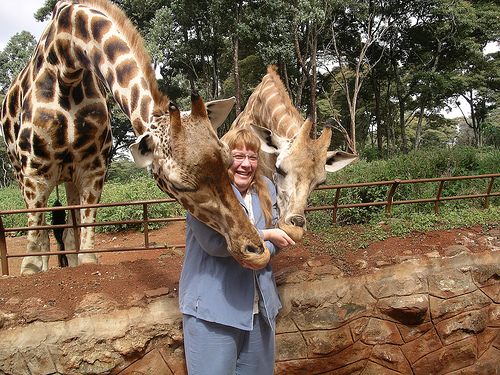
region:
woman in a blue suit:
[179, 128, 281, 373]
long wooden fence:
[1, 176, 498, 276]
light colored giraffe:
[229, 63, 356, 235]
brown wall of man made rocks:
[5, 254, 498, 370]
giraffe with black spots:
[1, 3, 269, 271]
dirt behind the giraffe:
[4, 218, 190, 276]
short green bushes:
[1, 148, 495, 233]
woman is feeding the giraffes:
[150, 97, 323, 357]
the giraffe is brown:
[114, 61, 337, 322]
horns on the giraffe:
[165, 95, 221, 163]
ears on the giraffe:
[131, 98, 234, 170]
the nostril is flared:
[239, 234, 262, 259]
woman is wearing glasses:
[234, 151, 256, 164]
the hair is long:
[227, 132, 274, 237]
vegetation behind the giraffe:
[5, 87, 480, 202]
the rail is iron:
[0, 181, 497, 253]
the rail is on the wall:
[11, 192, 493, 367]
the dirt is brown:
[23, 265, 180, 301]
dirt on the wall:
[10, 270, 198, 371]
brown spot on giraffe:
[7, 86, 20, 117]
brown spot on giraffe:
[17, 66, 34, 102]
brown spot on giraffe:
[31, 43, 48, 79]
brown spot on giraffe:
[44, 44, 62, 68]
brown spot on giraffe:
[31, 65, 57, 105]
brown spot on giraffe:
[18, 127, 34, 153]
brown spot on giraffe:
[72, 97, 108, 153]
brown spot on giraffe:
[101, 34, 130, 61]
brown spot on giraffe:
[115, 59, 138, 90]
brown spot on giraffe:
[128, 80, 141, 114]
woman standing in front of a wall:
[180, 129, 285, 374]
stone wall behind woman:
[0, 231, 497, 373]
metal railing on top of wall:
[306, 172, 498, 227]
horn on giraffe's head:
[167, 102, 182, 134]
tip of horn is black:
[168, 102, 176, 110]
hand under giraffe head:
[259, 228, 295, 250]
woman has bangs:
[227, 129, 260, 153]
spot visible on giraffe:
[115, 59, 137, 86]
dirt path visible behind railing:
[0, 216, 190, 273]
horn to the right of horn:
[191, 87, 206, 115]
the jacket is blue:
[187, 187, 278, 325]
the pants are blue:
[189, 321, 275, 373]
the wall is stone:
[285, 280, 497, 366]